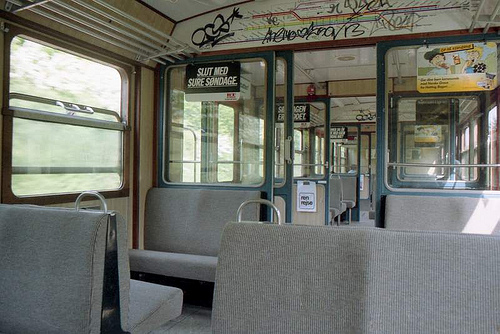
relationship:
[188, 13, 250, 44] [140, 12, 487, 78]
graffiti on wall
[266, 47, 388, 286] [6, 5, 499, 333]
inside of train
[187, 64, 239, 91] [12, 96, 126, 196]
sign on window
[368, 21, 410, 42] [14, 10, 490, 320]
tagging on bus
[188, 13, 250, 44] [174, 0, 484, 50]
graffiti on wall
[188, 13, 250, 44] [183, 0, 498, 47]
graffiti on wall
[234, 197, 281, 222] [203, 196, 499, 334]
handhold on seat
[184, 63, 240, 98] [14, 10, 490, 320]
sign on bus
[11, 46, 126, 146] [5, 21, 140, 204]
sky from window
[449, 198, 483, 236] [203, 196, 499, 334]
light on seat